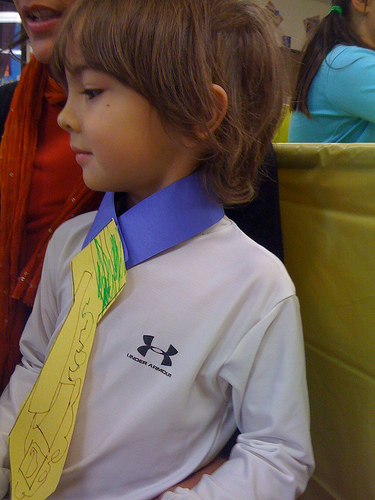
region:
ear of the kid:
[164, 68, 247, 150]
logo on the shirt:
[111, 328, 196, 390]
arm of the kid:
[201, 362, 334, 498]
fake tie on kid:
[52, 194, 159, 308]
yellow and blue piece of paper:
[15, 201, 200, 424]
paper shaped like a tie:
[0, 206, 201, 409]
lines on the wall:
[312, 191, 365, 398]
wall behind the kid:
[285, 191, 370, 319]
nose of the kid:
[46, 81, 92, 141]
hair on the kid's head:
[113, 11, 281, 115]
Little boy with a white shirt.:
[44, 11, 374, 463]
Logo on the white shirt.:
[93, 302, 217, 415]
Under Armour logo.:
[79, 307, 245, 457]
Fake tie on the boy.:
[30, 209, 328, 495]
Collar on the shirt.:
[68, 183, 326, 292]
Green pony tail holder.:
[306, 5, 366, 44]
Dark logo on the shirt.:
[111, 325, 235, 406]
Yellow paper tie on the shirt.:
[7, 307, 121, 495]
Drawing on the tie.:
[13, 341, 133, 414]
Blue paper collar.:
[86, 181, 284, 252]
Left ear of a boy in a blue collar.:
[195, 81, 228, 140]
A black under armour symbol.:
[136, 332, 177, 366]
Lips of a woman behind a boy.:
[17, 3, 62, 34]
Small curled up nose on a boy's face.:
[54, 87, 85, 134]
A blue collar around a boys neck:
[82, 170, 225, 268]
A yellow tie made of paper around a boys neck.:
[9, 219, 127, 499]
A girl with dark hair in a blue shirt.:
[288, 0, 374, 144]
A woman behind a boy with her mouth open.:
[0, 1, 286, 390]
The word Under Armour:
[126, 352, 172, 380]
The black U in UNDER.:
[126, 353, 132, 359]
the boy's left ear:
[191, 80, 225, 151]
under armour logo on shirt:
[122, 329, 186, 366]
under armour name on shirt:
[122, 354, 175, 392]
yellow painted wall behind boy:
[295, 249, 372, 498]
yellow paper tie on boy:
[4, 224, 124, 496]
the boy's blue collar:
[127, 176, 224, 270]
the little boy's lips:
[65, 135, 107, 172]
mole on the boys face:
[102, 100, 115, 115]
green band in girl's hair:
[327, 2, 342, 15]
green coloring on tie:
[96, 241, 120, 313]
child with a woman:
[4, 5, 267, 488]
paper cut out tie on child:
[13, 219, 119, 489]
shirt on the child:
[24, 208, 291, 496]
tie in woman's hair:
[321, 4, 352, 19]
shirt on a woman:
[289, 46, 374, 135]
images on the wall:
[260, 6, 324, 44]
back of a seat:
[305, 136, 345, 207]